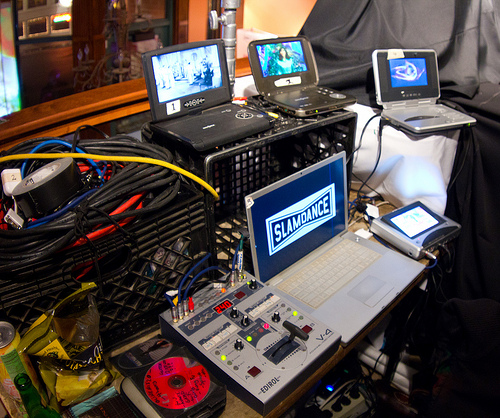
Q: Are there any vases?
A: No, there are no vases.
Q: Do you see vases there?
A: No, there are no vases.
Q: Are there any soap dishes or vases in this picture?
A: No, there are no vases or soap dishes.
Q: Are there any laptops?
A: Yes, there is a laptop.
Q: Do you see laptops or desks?
A: Yes, there is a laptop.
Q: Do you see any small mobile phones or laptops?
A: Yes, there is a small laptop.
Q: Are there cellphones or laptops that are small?
A: Yes, the laptop is small.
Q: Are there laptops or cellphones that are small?
A: Yes, the laptop is small.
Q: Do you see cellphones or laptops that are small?
A: Yes, the laptop is small.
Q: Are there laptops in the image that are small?
A: Yes, there is a small laptop.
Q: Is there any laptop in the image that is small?
A: Yes, there is a laptop that is small.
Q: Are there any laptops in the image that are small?
A: Yes, there is a laptop that is small.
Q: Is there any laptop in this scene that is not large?
A: Yes, there is a small laptop.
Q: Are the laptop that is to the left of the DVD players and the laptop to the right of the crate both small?
A: Yes, both the laptop and the laptop are small.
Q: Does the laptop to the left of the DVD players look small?
A: Yes, the laptop is small.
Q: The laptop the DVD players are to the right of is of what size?
A: The laptop is small.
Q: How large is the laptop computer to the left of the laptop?
A: The laptop is small.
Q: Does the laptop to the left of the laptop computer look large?
A: No, the laptop is small.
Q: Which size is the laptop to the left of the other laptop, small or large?
A: The laptop is small.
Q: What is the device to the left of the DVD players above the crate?
A: The device is a laptop.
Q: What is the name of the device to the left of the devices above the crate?
A: The device is a laptop.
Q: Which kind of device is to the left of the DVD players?
A: The device is a laptop.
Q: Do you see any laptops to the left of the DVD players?
A: Yes, there is a laptop to the left of the DVD players.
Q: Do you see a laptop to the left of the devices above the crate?
A: Yes, there is a laptop to the left of the DVD players.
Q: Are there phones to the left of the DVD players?
A: No, there is a laptop to the left of the DVD players.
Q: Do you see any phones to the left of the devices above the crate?
A: No, there is a laptop to the left of the DVD players.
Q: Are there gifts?
A: No, there are no gifts.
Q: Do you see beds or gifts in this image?
A: No, there are no gifts or beds.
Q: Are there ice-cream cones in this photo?
A: No, there are no ice-cream cones.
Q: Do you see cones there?
A: No, there are no cones.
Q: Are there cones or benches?
A: No, there are no cones or benches.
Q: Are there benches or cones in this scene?
A: No, there are no cones or benches.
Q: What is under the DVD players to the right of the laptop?
A: The crate is under the DVD players.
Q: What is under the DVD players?
A: The crate is under the DVD players.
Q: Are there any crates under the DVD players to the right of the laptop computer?
A: Yes, there is a crate under the DVD players.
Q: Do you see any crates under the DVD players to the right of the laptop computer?
A: Yes, there is a crate under the DVD players.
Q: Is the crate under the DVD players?
A: Yes, the crate is under the DVD players.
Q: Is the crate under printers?
A: No, the crate is under the DVD players.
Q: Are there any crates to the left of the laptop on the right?
A: Yes, there is a crate to the left of the laptop.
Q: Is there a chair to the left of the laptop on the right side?
A: No, there is a crate to the left of the laptop computer.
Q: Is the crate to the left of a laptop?
A: Yes, the crate is to the left of a laptop.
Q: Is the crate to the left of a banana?
A: No, the crate is to the left of a laptop.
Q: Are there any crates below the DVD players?
A: Yes, there is a crate below the DVD players.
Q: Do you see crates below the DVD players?
A: Yes, there is a crate below the DVD players.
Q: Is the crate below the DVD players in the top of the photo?
A: Yes, the crate is below the DVD players.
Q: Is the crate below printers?
A: No, the crate is below the DVD players.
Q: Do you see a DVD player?
A: Yes, there are DVD players.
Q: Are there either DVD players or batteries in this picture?
A: Yes, there are DVD players.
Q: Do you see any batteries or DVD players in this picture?
A: Yes, there are DVD players.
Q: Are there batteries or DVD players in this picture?
A: Yes, there are DVD players.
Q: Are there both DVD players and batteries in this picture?
A: No, there are DVD players but no batteries.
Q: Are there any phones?
A: No, there are no phones.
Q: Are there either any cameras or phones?
A: No, there are no phones or cameras.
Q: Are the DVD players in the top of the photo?
A: Yes, the DVD players are in the top of the image.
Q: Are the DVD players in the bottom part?
A: No, the DVD players are in the top of the image.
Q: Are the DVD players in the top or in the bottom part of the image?
A: The DVD players are in the top of the image.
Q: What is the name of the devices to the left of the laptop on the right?
A: The devices are DVD players.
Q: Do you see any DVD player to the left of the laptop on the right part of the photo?
A: Yes, there are DVD players to the left of the laptop.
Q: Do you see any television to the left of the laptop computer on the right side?
A: No, there are DVD players to the left of the laptop.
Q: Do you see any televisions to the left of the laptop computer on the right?
A: No, there are DVD players to the left of the laptop.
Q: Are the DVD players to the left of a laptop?
A: Yes, the DVD players are to the left of a laptop.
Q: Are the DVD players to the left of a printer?
A: No, the DVD players are to the left of a laptop.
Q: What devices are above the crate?
A: The devices are DVD players.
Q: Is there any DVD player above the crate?
A: Yes, there are DVD players above the crate.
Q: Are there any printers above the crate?
A: No, there are DVD players above the crate.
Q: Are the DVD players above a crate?
A: Yes, the DVD players are above a crate.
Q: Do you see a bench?
A: No, there are no benches.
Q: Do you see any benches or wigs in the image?
A: No, there are no benches or wigs.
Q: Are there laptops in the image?
A: Yes, there is a laptop.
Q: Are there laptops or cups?
A: Yes, there is a laptop.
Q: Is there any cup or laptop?
A: Yes, there is a laptop.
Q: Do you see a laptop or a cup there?
A: Yes, there is a laptop.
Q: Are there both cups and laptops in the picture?
A: No, there is a laptop but no cups.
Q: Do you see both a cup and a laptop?
A: No, there is a laptop but no cups.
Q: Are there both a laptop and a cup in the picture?
A: No, there is a laptop but no cups.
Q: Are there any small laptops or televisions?
A: Yes, there is a small laptop.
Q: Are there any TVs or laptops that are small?
A: Yes, the laptop is small.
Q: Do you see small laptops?
A: Yes, there is a small laptop.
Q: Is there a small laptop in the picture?
A: Yes, there is a small laptop.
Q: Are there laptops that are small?
A: Yes, there is a laptop that is small.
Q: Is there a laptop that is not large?
A: Yes, there is a small laptop.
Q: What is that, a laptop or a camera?
A: That is a laptop.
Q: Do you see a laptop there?
A: Yes, there is a laptop.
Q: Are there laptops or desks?
A: Yes, there is a laptop.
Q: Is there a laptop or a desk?
A: Yes, there is a laptop.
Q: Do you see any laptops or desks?
A: Yes, there is a laptop.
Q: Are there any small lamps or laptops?
A: Yes, there is a small laptop.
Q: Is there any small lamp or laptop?
A: Yes, there is a small laptop.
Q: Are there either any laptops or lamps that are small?
A: Yes, the laptop is small.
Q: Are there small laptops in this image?
A: Yes, there is a small laptop.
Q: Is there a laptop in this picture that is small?
A: Yes, there is a laptop that is small.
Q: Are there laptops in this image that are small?
A: Yes, there is a laptop that is small.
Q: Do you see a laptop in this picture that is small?
A: Yes, there is a laptop that is small.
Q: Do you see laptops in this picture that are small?
A: Yes, there is a laptop that is small.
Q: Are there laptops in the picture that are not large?
A: Yes, there is a small laptop.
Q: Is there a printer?
A: No, there are no printers.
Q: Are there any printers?
A: No, there are no printers.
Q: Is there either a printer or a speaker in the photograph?
A: No, there are no printers or speakers.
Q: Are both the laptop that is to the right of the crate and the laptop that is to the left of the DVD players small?
A: Yes, both the laptop and the laptop are small.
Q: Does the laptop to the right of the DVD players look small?
A: Yes, the laptop is small.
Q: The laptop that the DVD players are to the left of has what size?
A: The laptop computer is small.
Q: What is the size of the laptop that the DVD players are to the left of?
A: The laptop computer is small.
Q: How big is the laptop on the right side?
A: The laptop is small.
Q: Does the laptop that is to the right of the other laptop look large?
A: No, the laptop is small.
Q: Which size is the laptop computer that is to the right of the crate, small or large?
A: The laptop computer is small.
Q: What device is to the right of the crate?
A: The device is a laptop.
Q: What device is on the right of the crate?
A: The device is a laptop.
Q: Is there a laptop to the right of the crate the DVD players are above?
A: Yes, there is a laptop to the right of the crate.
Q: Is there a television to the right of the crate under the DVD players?
A: No, there is a laptop to the right of the crate.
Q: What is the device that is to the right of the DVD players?
A: The device is a laptop.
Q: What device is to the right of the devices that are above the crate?
A: The device is a laptop.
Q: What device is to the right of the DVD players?
A: The device is a laptop.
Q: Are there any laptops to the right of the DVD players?
A: Yes, there is a laptop to the right of the DVD players.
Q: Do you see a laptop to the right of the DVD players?
A: Yes, there is a laptop to the right of the DVD players.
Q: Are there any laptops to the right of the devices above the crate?
A: Yes, there is a laptop to the right of the DVD players.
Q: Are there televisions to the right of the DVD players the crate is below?
A: No, there is a laptop to the right of the DVD players.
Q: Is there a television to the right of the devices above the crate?
A: No, there is a laptop to the right of the DVD players.